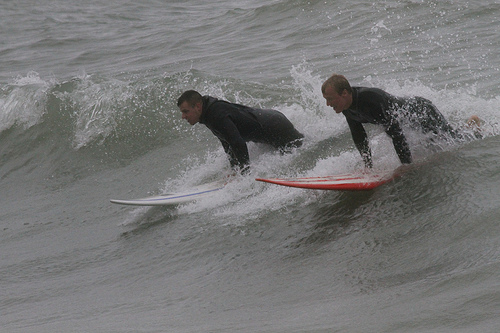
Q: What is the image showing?
A: It is showing an ocean.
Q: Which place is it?
A: It is an ocean.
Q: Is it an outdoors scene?
A: Yes, it is outdoors.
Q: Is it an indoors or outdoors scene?
A: It is outdoors.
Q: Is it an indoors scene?
A: No, it is outdoors.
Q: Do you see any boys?
A: No, there are no boys.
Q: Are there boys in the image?
A: No, there are no boys.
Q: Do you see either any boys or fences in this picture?
A: No, there are no boys or fences.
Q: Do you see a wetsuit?
A: Yes, there is a wetsuit.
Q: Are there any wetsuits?
A: Yes, there is a wetsuit.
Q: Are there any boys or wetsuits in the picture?
A: Yes, there is a wetsuit.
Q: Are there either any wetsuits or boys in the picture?
A: Yes, there is a wetsuit.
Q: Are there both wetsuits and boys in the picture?
A: No, there is a wetsuit but no boys.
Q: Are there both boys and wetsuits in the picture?
A: No, there is a wetsuit but no boys.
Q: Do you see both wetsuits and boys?
A: No, there is a wetsuit but no boys.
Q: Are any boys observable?
A: No, there are no boys.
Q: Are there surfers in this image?
A: Yes, there is a surfer.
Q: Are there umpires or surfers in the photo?
A: Yes, there is a surfer.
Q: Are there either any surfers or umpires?
A: Yes, there is a surfer.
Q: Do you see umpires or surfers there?
A: Yes, there is a surfer.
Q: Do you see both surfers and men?
A: Yes, there are both a surfer and a man.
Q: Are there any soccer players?
A: No, there are no soccer players.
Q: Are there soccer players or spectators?
A: No, there are no soccer players or spectators.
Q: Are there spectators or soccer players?
A: No, there are no soccer players or spectators.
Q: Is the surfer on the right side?
A: Yes, the surfer is on the right of the image.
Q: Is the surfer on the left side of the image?
A: No, the surfer is on the right of the image.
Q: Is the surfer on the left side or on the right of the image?
A: The surfer is on the right of the image.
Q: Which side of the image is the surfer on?
A: The surfer is on the right of the image.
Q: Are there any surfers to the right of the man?
A: Yes, there is a surfer to the right of the man.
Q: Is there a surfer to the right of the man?
A: Yes, there is a surfer to the right of the man.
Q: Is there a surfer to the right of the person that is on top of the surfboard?
A: Yes, there is a surfer to the right of the man.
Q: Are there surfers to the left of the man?
A: No, the surfer is to the right of the man.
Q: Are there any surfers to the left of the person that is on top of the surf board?
A: No, the surfer is to the right of the man.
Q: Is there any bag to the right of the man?
A: No, there is a surfer to the right of the man.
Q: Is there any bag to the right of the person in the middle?
A: No, there is a surfer to the right of the man.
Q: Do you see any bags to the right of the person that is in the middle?
A: No, there is a surfer to the right of the man.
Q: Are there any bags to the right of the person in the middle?
A: No, there is a surfer to the right of the man.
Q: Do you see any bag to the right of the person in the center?
A: No, there is a surfer to the right of the man.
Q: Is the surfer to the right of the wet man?
A: Yes, the surfer is to the right of the man.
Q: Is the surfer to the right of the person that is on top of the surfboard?
A: Yes, the surfer is to the right of the man.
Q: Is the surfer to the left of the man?
A: No, the surfer is to the right of the man.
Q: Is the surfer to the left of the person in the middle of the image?
A: No, the surfer is to the right of the man.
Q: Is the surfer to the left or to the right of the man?
A: The surfer is to the right of the man.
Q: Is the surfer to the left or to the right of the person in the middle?
A: The surfer is to the right of the man.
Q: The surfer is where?
A: The surfer is in the ocean.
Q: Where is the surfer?
A: The surfer is in the ocean.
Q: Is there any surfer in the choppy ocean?
A: Yes, there is a surfer in the ocean.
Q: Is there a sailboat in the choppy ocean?
A: No, there is a surfer in the ocean.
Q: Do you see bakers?
A: No, there are no bakers.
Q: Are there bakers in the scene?
A: No, there are no bakers.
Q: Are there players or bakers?
A: No, there are no bakers or players.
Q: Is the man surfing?
A: Yes, the man is surfing.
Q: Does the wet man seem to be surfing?
A: Yes, the man is surfing.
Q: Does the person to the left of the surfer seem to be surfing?
A: Yes, the man is surfing.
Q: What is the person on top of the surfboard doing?
A: The man is surfing.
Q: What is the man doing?
A: The man is surfing.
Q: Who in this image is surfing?
A: The man is surfing.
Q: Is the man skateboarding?
A: No, the man is surfing.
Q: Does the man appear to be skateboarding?
A: No, the man is surfing.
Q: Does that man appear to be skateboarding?
A: No, the man is surfing.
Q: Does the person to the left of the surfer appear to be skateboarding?
A: No, the man is surfing.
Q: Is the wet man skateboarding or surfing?
A: The man is surfing.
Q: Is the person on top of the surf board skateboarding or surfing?
A: The man is surfing.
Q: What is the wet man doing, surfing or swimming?
A: The man is surfing.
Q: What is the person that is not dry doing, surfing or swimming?
A: The man is surfing.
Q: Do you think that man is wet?
A: Yes, the man is wet.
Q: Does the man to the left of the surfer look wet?
A: Yes, the man is wet.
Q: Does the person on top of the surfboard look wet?
A: Yes, the man is wet.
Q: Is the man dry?
A: No, the man is wet.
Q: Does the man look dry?
A: No, the man is wet.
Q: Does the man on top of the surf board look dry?
A: No, the man is wet.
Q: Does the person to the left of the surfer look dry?
A: No, the man is wet.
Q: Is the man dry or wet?
A: The man is wet.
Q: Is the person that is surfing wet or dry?
A: The man is wet.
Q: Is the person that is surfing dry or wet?
A: The man is wet.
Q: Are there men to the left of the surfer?
A: Yes, there is a man to the left of the surfer.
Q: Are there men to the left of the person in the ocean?
A: Yes, there is a man to the left of the surfer.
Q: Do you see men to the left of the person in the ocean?
A: Yes, there is a man to the left of the surfer.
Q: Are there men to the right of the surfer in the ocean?
A: No, the man is to the left of the surfer.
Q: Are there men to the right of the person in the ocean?
A: No, the man is to the left of the surfer.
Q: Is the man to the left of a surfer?
A: Yes, the man is to the left of a surfer.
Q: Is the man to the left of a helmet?
A: No, the man is to the left of a surfer.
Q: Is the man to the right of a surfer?
A: No, the man is to the left of a surfer.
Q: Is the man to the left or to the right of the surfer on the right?
A: The man is to the left of the surfer.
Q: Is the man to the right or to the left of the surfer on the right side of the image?
A: The man is to the left of the surfer.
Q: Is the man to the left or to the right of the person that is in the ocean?
A: The man is to the left of the surfer.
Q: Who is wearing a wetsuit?
A: The man is wearing a wetsuit.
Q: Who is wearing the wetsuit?
A: The man is wearing a wetsuit.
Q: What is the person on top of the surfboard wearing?
A: The man is wearing a wetsuit.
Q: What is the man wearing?
A: The man is wearing a wetsuit.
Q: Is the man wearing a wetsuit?
A: Yes, the man is wearing a wetsuit.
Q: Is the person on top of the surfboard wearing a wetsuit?
A: Yes, the man is wearing a wetsuit.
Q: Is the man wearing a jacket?
A: No, the man is wearing a wetsuit.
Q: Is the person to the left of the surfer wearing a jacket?
A: No, the man is wearing a wetsuit.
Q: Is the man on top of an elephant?
A: No, the man is on top of the surfboard.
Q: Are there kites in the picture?
A: No, there are no kites.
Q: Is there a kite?
A: No, there are no kites.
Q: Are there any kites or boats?
A: No, there are no kites or boats.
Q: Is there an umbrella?
A: No, there are no umbrellas.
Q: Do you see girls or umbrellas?
A: No, there are no umbrellas or girls.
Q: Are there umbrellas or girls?
A: No, there are no umbrellas or girls.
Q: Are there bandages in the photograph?
A: No, there are no bandages.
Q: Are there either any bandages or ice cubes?
A: No, there are no bandages or ice cubes.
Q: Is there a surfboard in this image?
A: Yes, there is a surfboard.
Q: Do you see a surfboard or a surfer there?
A: Yes, there is a surfboard.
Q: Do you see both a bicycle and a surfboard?
A: No, there is a surfboard but no bicycles.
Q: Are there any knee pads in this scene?
A: No, there are no knee pads.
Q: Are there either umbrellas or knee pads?
A: No, there are no knee pads or umbrellas.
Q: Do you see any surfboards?
A: Yes, there is a surfboard.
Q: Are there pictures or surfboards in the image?
A: Yes, there is a surfboard.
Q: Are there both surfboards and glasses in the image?
A: No, there is a surfboard but no glasses.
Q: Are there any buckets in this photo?
A: No, there are no buckets.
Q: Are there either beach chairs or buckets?
A: No, there are no buckets or beach chairs.